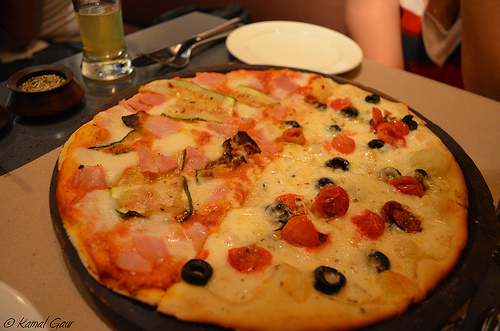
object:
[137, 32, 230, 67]
fork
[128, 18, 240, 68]
knife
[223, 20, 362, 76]
plate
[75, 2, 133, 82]
glass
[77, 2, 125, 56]
beer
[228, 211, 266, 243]
cheese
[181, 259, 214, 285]
olive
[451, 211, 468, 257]
crust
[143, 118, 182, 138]
ham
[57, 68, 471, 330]
pizza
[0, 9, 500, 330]
table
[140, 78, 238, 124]
zucchini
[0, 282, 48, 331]
plate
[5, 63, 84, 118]
bowl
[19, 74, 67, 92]
spices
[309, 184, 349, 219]
tomatoes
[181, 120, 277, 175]
toppings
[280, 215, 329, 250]
pepperoni